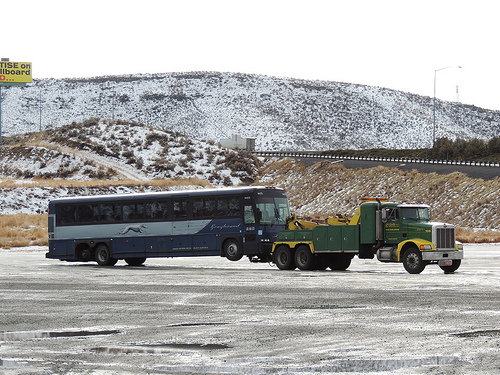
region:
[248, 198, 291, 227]
windshield on bus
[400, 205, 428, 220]
windshield on truck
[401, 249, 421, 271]
front right tire on truck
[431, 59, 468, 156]
street light next to road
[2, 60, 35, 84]
sign on top of hill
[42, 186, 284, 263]
bus behind truck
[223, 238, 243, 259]
tire on bus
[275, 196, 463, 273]
green truck in front of bus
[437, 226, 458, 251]
radiator grill on truck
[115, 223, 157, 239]
dog design on bus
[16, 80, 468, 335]
This is a truck towing a bus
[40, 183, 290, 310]
this is a bus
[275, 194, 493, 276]
this truck is heavy duty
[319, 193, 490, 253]
the truck is green and yellow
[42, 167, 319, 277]
this bus is gray and blue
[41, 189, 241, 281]
this is a greyhouse bus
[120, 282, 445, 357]
the ground here is frozen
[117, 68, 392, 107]
the hills have snow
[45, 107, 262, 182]
there is brush with snow here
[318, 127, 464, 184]
this is a road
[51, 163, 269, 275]
passenger bus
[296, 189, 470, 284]
green and yellow truck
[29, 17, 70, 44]
white clouds in blue sky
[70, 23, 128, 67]
white clouds in blue sky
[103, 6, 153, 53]
white clouds in blue sky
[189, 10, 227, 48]
white clouds in blue sky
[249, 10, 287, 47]
white clouds in blue sky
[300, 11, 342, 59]
white clouds in blue sky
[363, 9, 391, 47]
white clouds in blue sky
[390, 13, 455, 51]
white clouds in blue sky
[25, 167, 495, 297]
green truck hauling a bus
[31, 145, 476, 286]
truck hauling a blue bus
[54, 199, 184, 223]
windows on side of bus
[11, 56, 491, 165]
small snowy mountain range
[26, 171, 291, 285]
broken down blue bus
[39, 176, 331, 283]
broken down greyhound bus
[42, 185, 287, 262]
blue and silver bus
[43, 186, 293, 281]
blue and silver greyhound bus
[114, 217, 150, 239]
greyhound logo on bus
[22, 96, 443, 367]
a bus being towed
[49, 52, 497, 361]
a truck being towed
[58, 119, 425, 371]
a tow truck being towed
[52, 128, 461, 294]
a greyhound bus being towed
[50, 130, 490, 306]
a greyhouse bus being pulled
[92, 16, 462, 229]
snow covering the ground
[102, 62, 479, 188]
white snow covering the ground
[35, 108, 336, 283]
a blue greyhound bus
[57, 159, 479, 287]
a greyhound bus being pulled by a green tow truck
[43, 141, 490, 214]
a green tow truck being pulled by a bus